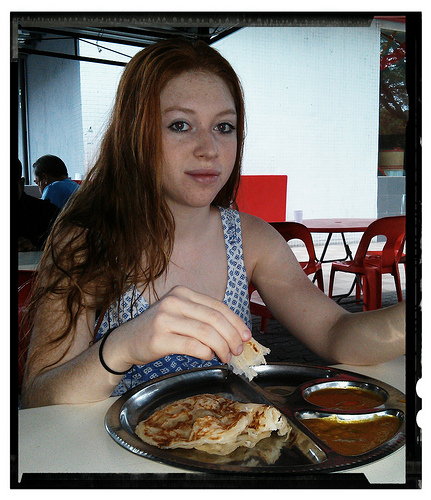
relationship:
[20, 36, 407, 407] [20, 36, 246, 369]
wall has hair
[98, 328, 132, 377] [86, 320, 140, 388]
hair band on wrist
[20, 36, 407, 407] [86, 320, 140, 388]
wall has wrist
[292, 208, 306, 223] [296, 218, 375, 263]
cup on table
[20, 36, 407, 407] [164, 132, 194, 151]
wall has freckles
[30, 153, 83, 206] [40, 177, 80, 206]
man wearing shirt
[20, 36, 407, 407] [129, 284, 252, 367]
wall has hand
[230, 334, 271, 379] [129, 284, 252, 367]
food in hand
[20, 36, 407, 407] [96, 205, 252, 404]
wall wearing blouse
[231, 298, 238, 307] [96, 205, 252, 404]
design on blouse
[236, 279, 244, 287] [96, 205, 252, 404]
design on blouse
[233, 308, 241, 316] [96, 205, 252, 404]
design on blouse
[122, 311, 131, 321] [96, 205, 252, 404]
design on blouse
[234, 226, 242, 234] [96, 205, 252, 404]
design on blouse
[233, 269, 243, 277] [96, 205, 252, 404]
design on blouse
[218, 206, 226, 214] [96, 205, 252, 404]
design on blouse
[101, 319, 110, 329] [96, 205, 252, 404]
design on blouse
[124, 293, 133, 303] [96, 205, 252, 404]
design on blouse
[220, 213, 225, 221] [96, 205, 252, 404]
design on blouse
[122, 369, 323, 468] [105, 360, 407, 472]
section of tray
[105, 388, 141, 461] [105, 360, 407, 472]
edge of tray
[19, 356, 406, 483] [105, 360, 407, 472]
table under tray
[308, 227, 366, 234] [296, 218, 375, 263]
edge of table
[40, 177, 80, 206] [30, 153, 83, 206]
shirt on man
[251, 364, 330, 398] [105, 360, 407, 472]
section on tray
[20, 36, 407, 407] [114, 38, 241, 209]
wall has head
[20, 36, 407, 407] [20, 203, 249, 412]
wall has arm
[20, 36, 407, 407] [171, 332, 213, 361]
wall has finger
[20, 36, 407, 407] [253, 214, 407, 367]
wall has arm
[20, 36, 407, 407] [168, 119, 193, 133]
wall has eye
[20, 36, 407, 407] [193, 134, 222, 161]
wall has nose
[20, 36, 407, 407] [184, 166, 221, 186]
wall has mouth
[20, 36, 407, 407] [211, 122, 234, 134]
wall has eye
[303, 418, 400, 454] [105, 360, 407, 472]
sauce on tray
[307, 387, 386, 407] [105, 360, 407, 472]
sauce on tray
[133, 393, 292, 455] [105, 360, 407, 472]
bread on tray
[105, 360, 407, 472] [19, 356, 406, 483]
tray on table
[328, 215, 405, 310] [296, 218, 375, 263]
chair at table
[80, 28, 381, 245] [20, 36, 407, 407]
wall behind wall